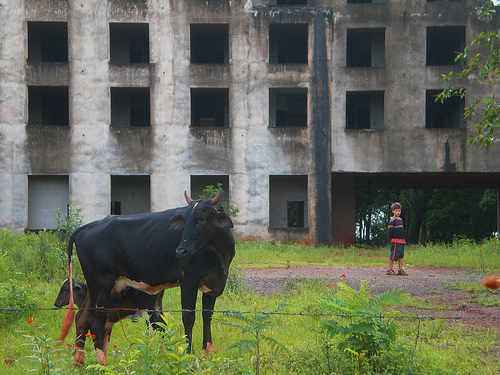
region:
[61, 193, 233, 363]
A black bull in the grass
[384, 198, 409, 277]
A kid in black and red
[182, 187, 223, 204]
Short horns on a bull's head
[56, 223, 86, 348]
Tail on the back of a bull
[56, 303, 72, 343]
Tufted end of a bull's tail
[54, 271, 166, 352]
A black calf near a bull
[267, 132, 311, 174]
Stained concrete on a building's wall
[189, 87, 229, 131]
Window on the side of a building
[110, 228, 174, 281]
Black fur on a bovine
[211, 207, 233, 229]
A bovine's left ear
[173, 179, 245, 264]
head of a cow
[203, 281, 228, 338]
leg of a cow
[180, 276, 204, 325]
leg of a cow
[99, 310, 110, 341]
leg of a cow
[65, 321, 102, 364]
leg of a cow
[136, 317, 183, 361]
leg of a cow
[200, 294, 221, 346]
a leg of a cow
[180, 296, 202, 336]
a leg of a cow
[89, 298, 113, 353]
a leg of a cow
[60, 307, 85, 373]
a leg of a cow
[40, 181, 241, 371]
cow standing in the green grass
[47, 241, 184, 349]
baby cow standing behind the larger cow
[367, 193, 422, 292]
little boy standing near cow in the dirt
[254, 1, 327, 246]
old run down cement building with windows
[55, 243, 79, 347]
long red tail on adult cow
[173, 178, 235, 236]
horns on head of adult cow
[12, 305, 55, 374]
red flowers on the small plants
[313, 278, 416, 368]
fat short green fern growing in field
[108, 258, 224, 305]
white belly on black haired cow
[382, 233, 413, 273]
boy wearing black and red shorts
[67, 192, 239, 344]
black cow standing in field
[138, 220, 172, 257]
rib cage of cow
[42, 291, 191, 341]
baby cow behind cow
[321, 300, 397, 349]
short bush in green field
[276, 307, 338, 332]
barbed wire on gate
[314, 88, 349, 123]
black mark on building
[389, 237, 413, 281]
kid in black pants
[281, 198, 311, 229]
door inside of porch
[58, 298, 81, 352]
brown tuft on cows tail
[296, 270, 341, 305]
patch of dirt in field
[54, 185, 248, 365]
black cow with orange tail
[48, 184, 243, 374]
cow standing near calf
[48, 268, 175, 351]
black calf near mother cow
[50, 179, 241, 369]
black cow with horns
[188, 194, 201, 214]
white spot on cow forehead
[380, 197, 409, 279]
boy standing beyond cow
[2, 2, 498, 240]
abandoned stone building in background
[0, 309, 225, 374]
orange flowers in front of cow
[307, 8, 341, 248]
long black area on building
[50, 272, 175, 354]
small calf facing left